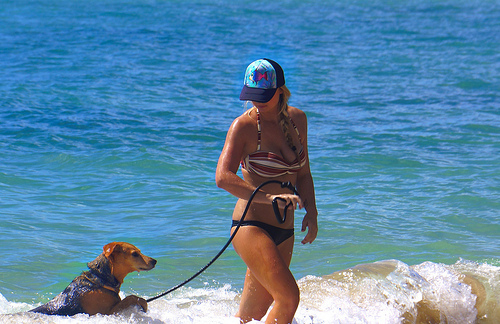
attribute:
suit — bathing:
[237, 111, 305, 250]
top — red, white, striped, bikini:
[234, 115, 326, 186]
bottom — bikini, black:
[224, 216, 307, 248]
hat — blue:
[238, 58, 293, 109]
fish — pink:
[244, 66, 274, 86]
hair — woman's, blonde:
[271, 80, 301, 130]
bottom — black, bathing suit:
[226, 215, 305, 251]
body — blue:
[4, 4, 494, 323]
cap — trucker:
[235, 57, 289, 114]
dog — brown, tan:
[25, 234, 155, 323]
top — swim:
[236, 106, 309, 182]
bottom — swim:
[225, 214, 303, 254]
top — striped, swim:
[242, 100, 310, 180]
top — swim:
[239, 94, 315, 181]